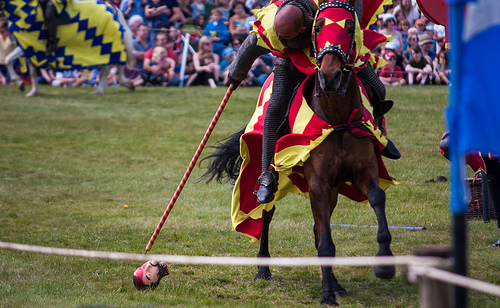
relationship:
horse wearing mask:
[200, 1, 394, 307] [310, 4, 357, 69]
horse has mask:
[200, 1, 394, 307] [310, 4, 357, 69]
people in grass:
[0, 2, 451, 86] [0, 83, 499, 306]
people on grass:
[0, 2, 451, 86] [0, 83, 499, 306]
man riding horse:
[228, 2, 402, 204] [200, 1, 394, 307]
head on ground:
[133, 257, 170, 293] [1, 83, 499, 306]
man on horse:
[228, 2, 402, 204] [200, 1, 394, 307]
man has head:
[228, 2, 402, 204] [272, 4, 312, 41]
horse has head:
[200, 1, 394, 307] [309, 1, 365, 93]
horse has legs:
[200, 1, 394, 307] [254, 179, 397, 307]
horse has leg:
[200, 1, 394, 307] [359, 176, 403, 281]